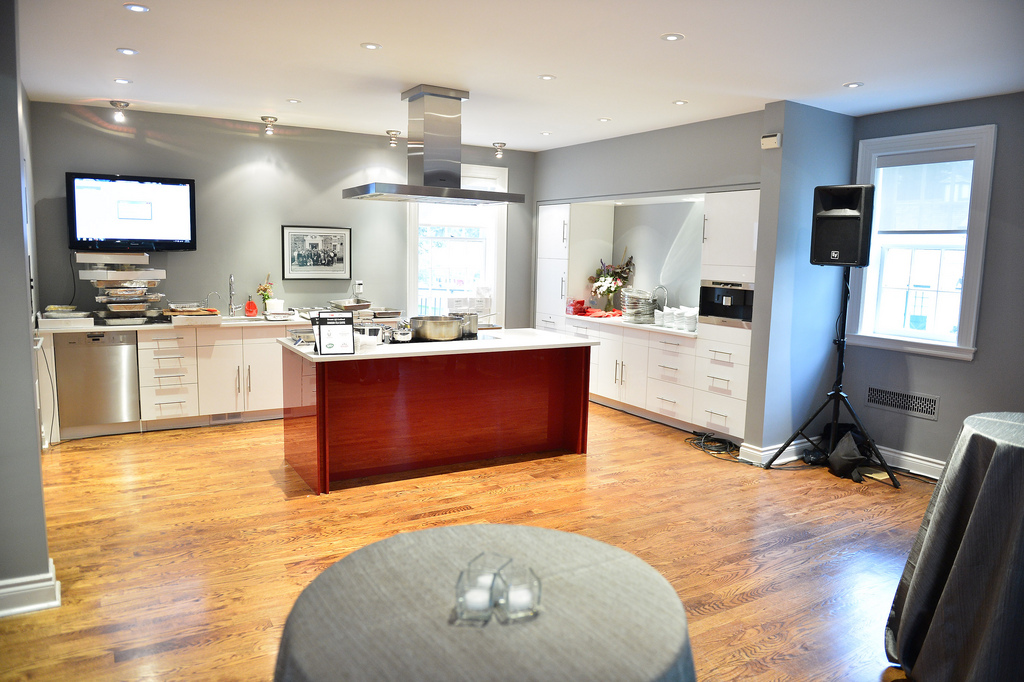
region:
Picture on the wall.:
[277, 218, 366, 285]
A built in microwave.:
[686, 269, 757, 330]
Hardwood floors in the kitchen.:
[137, 471, 254, 615]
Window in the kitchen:
[830, 127, 996, 350]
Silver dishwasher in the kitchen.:
[46, 320, 145, 445]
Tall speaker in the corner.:
[798, 151, 896, 477]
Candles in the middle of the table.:
[440, 542, 552, 629]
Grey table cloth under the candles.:
[269, 538, 412, 665]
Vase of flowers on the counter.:
[251, 268, 280, 316]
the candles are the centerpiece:
[446, 546, 545, 626]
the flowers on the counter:
[590, 250, 639, 315]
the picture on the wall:
[282, 227, 353, 281]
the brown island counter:
[274, 325, 589, 497]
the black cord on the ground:
[687, 429, 818, 475]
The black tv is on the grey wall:
[14, 155, 286, 295]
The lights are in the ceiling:
[73, 9, 285, 146]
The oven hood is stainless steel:
[321, 57, 609, 273]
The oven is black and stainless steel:
[686, 246, 773, 358]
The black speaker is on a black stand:
[750, 136, 938, 526]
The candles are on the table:
[298, 461, 627, 659]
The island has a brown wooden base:
[231, 307, 664, 570]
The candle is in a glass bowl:
[415, 543, 586, 638]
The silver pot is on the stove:
[393, 281, 542, 398]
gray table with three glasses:
[248, 486, 752, 680]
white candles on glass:
[457, 535, 535, 625]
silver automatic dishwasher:
[53, 332, 143, 440]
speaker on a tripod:
[757, 175, 895, 489]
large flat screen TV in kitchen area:
[66, 167, 194, 257]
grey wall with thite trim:
[760, 104, 1007, 474]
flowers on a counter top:
[580, 241, 644, 314]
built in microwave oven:
[694, 275, 761, 330]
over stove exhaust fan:
[332, 77, 529, 208]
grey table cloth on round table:
[280, 515, 705, 678]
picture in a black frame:
[275, 222, 355, 286]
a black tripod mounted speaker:
[764, 178, 905, 485]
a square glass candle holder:
[497, 565, 542, 626]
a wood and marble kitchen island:
[277, 322, 594, 494]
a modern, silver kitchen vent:
[336, 81, 529, 212]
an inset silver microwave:
[694, 276, 759, 330]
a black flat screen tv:
[62, 166, 199, 253]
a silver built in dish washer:
[48, 330, 147, 442]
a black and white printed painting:
[277, 223, 357, 282]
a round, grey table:
[260, 520, 703, 680]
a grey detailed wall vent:
[859, 382, 942, 424]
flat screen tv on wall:
[57, 130, 236, 283]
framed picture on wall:
[247, 168, 396, 292]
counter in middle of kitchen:
[220, 317, 617, 501]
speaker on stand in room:
[756, 140, 922, 521]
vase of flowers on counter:
[564, 204, 675, 341]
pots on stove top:
[361, 296, 517, 374]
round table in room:
[235, 497, 755, 676]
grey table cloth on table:
[823, 387, 1019, 679]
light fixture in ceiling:
[84, 68, 158, 142]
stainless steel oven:
[683, 264, 808, 350]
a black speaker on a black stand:
[757, 180, 903, 490]